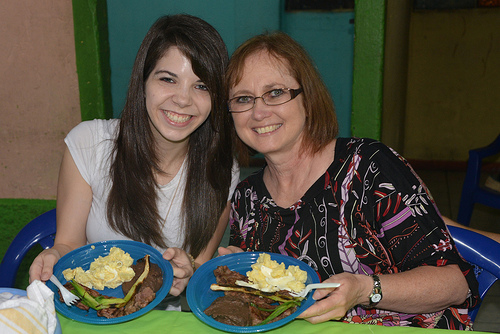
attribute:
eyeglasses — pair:
[235, 89, 308, 112]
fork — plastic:
[291, 282, 332, 296]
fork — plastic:
[276, 273, 351, 307]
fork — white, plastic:
[281, 283, 343, 307]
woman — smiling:
[219, 60, 327, 132]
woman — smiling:
[135, 41, 229, 139]